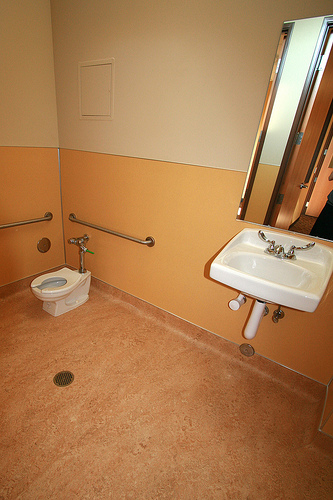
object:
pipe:
[242, 297, 265, 342]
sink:
[208, 228, 331, 313]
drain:
[52, 370, 73, 388]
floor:
[0, 296, 332, 500]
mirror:
[236, 14, 332, 238]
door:
[264, 26, 333, 229]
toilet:
[27, 266, 90, 319]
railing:
[67, 215, 155, 248]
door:
[79, 63, 111, 117]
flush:
[84, 248, 90, 256]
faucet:
[274, 245, 292, 261]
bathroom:
[0, 0, 332, 493]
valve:
[270, 310, 283, 325]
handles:
[286, 242, 315, 254]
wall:
[1, 0, 332, 364]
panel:
[77, 61, 114, 121]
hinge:
[294, 132, 303, 145]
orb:
[238, 343, 252, 358]